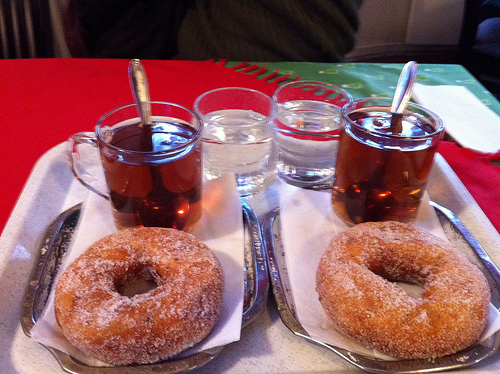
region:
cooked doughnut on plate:
[43, 211, 237, 371]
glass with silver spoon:
[64, 63, 206, 236]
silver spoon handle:
[116, 51, 163, 131]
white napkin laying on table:
[411, 76, 497, 161]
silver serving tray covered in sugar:
[21, 201, 61, 332]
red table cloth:
[5, 60, 90, 125]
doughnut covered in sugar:
[50, 220, 225, 367]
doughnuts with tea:
[2, 90, 497, 370]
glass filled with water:
[193, 61, 273, 196]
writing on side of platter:
[249, 208, 266, 277]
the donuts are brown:
[320, 235, 498, 347]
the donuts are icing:
[311, 225, 483, 339]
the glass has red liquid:
[336, 109, 443, 217]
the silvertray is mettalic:
[251, 216, 285, 310]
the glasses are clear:
[205, 83, 328, 179]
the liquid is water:
[206, 95, 327, 177]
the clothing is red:
[20, 80, 120, 118]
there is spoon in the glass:
[122, 65, 159, 132]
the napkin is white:
[275, 213, 315, 309]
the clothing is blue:
[339, 67, 394, 94]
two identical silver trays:
[16, 111, 495, 373]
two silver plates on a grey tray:
[8, 121, 498, 372]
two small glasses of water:
[180, 76, 361, 194]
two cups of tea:
[74, 43, 473, 245]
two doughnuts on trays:
[47, 219, 482, 372]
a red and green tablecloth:
[3, 46, 498, 162]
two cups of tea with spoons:
[50, 52, 488, 248]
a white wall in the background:
[355, 4, 480, 71]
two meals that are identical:
[31, 60, 489, 372]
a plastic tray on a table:
[5, 46, 498, 368]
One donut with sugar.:
[51, 224, 223, 366]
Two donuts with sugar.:
[53, 219, 493, 365]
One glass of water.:
[193, 85, 278, 198]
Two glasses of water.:
[192, 77, 354, 197]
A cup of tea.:
[63, 99, 203, 230]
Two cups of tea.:
[66, 95, 445, 231]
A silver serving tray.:
[18, 196, 271, 371]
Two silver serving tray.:
[18, 197, 499, 372]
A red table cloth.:
[1, 57, 498, 232]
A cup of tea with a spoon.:
[64, 56, 204, 232]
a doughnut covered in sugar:
[41, 222, 233, 369]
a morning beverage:
[67, 56, 228, 238]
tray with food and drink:
[0, 55, 498, 369]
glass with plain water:
[187, 80, 286, 195]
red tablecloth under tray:
[6, 60, 112, 117]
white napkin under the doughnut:
[39, 158, 246, 344]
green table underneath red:
[320, 52, 483, 117]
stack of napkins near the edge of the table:
[398, 71, 498, 150]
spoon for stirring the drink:
[112, 53, 194, 245]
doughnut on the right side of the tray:
[302, 212, 488, 362]